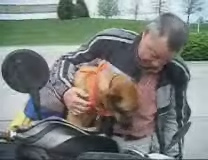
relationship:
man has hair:
[21, 11, 191, 158] [143, 13, 188, 52]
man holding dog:
[43, 13, 191, 160] [78, 57, 145, 141]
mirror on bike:
[2, 42, 52, 119] [19, 80, 44, 155]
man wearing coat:
[43, 13, 191, 160] [76, 27, 205, 127]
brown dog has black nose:
[65, 57, 141, 131] [101, 91, 143, 128]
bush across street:
[184, 35, 207, 58] [34, 22, 76, 39]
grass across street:
[35, 24, 71, 32] [195, 63, 207, 126]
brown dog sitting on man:
[65, 57, 141, 131] [21, 11, 191, 158]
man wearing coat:
[21, 11, 191, 158] [47, 27, 192, 160]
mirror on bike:
[0, 48, 50, 93] [1, 107, 198, 157]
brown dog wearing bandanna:
[65, 57, 141, 131] [77, 69, 115, 117]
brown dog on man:
[65, 58, 139, 131] [49, 11, 190, 158]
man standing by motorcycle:
[43, 13, 191, 160] [4, 48, 161, 158]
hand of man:
[60, 84, 95, 120] [21, 11, 191, 158]